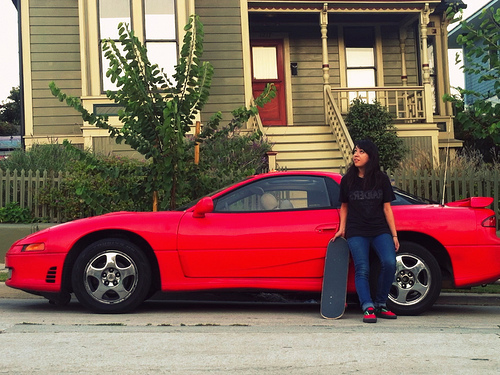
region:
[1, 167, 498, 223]
A small wooden fence.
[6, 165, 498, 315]
A red sports car with two-doors, parked along the side of the road.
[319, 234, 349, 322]
A black skateboard propped up against a car.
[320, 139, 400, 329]
A girl looking up, holding a skateboard beside her.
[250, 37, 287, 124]
A wooden front door with a window.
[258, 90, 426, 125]
A front porch on a house.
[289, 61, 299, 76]
A small black mailbox hung against the house.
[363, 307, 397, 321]
A pair of red and black shoes.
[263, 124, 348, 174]
Stairs in front of a house.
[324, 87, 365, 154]
A beige handrail.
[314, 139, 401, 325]
girl with a skateboard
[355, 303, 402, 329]
red and black sneakers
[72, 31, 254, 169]
green tree in front of house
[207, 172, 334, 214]
window of the red car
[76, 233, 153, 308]
black tire with chrome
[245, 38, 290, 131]
red door on the house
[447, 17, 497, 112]
blue house next door to the green house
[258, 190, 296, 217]
seat of the red car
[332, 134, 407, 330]
girl with black shirt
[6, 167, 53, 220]
wooden fence in front of house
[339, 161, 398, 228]
The black t-shirt the girl is wearing.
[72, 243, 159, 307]
The front tire of the car.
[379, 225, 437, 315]
The back tire of the car.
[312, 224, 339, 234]
The door handle on the car.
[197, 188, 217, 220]
The side view mirror of the car.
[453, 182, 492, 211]
The wing on the back of the car.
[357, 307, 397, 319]
The red and black sneakers the girl is wearing.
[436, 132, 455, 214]
The antennae on the car.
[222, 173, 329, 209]
The driver door window.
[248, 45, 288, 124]
The front door of the house.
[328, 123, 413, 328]
A woman standing by a red sports car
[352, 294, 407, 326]
The woman has red shoes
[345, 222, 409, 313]
The woman is wearing blue jeans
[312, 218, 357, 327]
The woman is holding a skateboard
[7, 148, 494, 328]
The sports car is red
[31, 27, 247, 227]
A tree with green leaves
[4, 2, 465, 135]
A house with grey siding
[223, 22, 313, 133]
The front door of home is brown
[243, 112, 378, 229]
The stairs to the home are off white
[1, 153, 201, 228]
The picket fence is grey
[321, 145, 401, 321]
A young female skate boarder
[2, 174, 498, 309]
A red colored sports coupe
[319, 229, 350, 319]
Skateboard with a black deck on it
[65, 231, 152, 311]
Front driver side tire of a sports car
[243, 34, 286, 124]
A red door with a medium window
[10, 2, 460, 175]
olive colored house with beige trim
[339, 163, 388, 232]
a black short-sleeved tee-shirt with a word graphic printed on it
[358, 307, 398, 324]
a pair of red and black skateboarding shoes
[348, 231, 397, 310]
a pair of female tight fit blue jeans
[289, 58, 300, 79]
small black mailbox on front porch of olive colored house